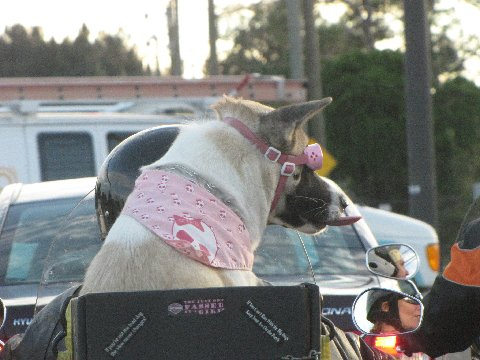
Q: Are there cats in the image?
A: No, there are no cats.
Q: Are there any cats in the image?
A: No, there are no cats.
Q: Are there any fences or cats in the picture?
A: No, there are no cats or fences.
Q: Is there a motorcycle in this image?
A: Yes, there is a motorcycle.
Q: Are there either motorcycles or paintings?
A: Yes, there is a motorcycle.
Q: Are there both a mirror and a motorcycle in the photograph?
A: Yes, there are both a motorcycle and a mirror.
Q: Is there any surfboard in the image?
A: No, there are no surfboards.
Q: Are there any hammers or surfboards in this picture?
A: No, there are no surfboards or hammers.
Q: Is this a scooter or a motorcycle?
A: This is a motorcycle.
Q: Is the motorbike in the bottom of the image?
A: Yes, the motorbike is in the bottom of the image.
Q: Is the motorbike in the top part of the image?
A: No, the motorbike is in the bottom of the image.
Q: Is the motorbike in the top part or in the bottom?
A: The motorbike is in the bottom of the image.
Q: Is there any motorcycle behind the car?
A: Yes, there is a motorcycle behind the car.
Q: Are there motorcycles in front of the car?
A: No, the motorcycle is behind the car.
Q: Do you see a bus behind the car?
A: No, there is a motorcycle behind the car.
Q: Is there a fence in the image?
A: No, there are no fences.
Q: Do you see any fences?
A: No, there are no fences.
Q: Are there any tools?
A: No, there are no tools.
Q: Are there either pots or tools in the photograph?
A: No, there are no tools or pots.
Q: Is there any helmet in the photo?
A: Yes, there is a helmet.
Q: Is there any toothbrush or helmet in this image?
A: Yes, there is a helmet.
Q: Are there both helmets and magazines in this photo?
A: No, there is a helmet but no magazines.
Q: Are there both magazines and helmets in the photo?
A: No, there is a helmet but no magazines.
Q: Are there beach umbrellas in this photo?
A: No, there are no beach umbrellas.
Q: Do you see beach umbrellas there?
A: No, there are no beach umbrellas.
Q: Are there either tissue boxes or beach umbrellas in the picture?
A: No, there are no beach umbrellas or tissue boxes.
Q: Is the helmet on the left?
A: Yes, the helmet is on the left of the image.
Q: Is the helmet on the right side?
A: No, the helmet is on the left of the image.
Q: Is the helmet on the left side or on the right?
A: The helmet is on the left of the image.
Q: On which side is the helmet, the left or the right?
A: The helmet is on the left of the image.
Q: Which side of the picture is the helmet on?
A: The helmet is on the left of the image.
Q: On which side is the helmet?
A: The helmet is on the left of the image.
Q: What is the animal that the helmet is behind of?
A: The animal is a dog.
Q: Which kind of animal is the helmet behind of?
A: The helmet is behind the dog.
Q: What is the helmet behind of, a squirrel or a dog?
A: The helmet is behind a dog.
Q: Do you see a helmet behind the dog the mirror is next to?
A: Yes, there is a helmet behind the dog.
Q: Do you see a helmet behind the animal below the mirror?
A: Yes, there is a helmet behind the dog.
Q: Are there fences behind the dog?
A: No, there is a helmet behind the dog.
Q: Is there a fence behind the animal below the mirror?
A: No, there is a helmet behind the dog.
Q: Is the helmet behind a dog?
A: Yes, the helmet is behind a dog.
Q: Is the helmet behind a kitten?
A: No, the helmet is behind a dog.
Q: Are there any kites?
A: No, there are no kites.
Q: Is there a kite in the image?
A: No, there are no kites.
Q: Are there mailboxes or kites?
A: No, there are no kites or mailboxes.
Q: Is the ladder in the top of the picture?
A: Yes, the ladder is in the top of the image.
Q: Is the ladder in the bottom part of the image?
A: No, the ladder is in the top of the image.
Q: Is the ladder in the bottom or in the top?
A: The ladder is in the top of the image.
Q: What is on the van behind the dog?
A: The ladder is on the van.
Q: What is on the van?
A: The ladder is on the van.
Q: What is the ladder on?
A: The ladder is on the van.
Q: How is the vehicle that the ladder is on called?
A: The vehicle is a van.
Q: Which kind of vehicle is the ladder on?
A: The ladder is on the van.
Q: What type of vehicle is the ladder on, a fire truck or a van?
A: The ladder is on a van.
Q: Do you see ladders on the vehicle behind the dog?
A: Yes, there is a ladder on the van.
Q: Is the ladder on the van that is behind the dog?
A: Yes, the ladder is on the van.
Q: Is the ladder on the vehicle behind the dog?
A: Yes, the ladder is on the van.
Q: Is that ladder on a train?
A: No, the ladder is on the van.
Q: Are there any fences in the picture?
A: No, there are no fences.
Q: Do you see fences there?
A: No, there are no fences.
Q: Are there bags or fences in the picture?
A: No, there are no fences or bags.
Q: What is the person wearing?
A: The person is wearing a helmet.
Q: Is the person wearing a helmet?
A: Yes, the person is wearing a helmet.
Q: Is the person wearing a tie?
A: No, the person is wearing a helmet.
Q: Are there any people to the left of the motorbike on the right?
A: Yes, there is a person to the left of the motorcycle.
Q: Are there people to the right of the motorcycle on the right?
A: No, the person is to the left of the motorbike.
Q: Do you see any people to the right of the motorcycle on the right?
A: No, the person is to the left of the motorbike.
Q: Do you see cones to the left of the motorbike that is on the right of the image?
A: No, there is a person to the left of the motorbike.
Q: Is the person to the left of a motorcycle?
A: Yes, the person is to the left of a motorcycle.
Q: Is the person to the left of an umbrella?
A: No, the person is to the left of a motorcycle.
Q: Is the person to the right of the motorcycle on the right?
A: No, the person is to the left of the motorbike.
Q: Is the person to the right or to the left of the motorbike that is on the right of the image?
A: The person is to the left of the motorbike.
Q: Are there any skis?
A: No, there are no skis.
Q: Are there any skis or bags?
A: No, there are no skis or bags.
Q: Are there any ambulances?
A: No, there are no ambulances.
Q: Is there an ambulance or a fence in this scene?
A: No, there are no ambulances or fences.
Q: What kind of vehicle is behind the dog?
A: The vehicle is a van.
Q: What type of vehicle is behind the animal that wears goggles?
A: The vehicle is a van.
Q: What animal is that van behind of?
A: The van is behind the dog.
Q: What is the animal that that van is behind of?
A: The animal is a dog.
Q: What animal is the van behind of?
A: The van is behind the dog.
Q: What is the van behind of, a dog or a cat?
A: The van is behind a dog.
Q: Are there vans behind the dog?
A: Yes, there is a van behind the dog.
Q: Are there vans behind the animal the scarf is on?
A: Yes, there is a van behind the dog.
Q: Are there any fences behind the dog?
A: No, there is a van behind the dog.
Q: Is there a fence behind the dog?
A: No, there is a van behind the dog.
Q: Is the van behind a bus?
A: No, the van is behind the dog.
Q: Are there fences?
A: No, there are no fences.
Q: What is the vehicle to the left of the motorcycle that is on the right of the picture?
A: The vehicle is a car.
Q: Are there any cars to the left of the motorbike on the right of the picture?
A: Yes, there is a car to the left of the motorbike.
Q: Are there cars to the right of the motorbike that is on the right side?
A: No, the car is to the left of the motorbike.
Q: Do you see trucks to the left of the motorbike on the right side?
A: No, there is a car to the left of the motorbike.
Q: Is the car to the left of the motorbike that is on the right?
A: Yes, the car is to the left of the motorcycle.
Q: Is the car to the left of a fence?
A: No, the car is to the left of the motorcycle.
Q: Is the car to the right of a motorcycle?
A: No, the car is to the left of a motorcycle.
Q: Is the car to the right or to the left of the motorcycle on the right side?
A: The car is to the left of the motorcycle.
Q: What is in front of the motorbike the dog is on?
A: The car is in front of the motorcycle.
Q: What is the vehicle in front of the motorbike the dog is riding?
A: The vehicle is a car.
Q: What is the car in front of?
A: The car is in front of the motorcycle.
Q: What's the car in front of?
A: The car is in front of the motorcycle.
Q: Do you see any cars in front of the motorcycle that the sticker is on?
A: Yes, there is a car in front of the motorbike.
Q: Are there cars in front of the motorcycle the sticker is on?
A: Yes, there is a car in front of the motorbike.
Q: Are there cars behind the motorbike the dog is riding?
A: No, the car is in front of the motorbike.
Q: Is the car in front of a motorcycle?
A: Yes, the car is in front of a motorcycle.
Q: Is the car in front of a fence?
A: No, the car is in front of a motorcycle.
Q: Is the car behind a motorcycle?
A: No, the car is in front of a motorcycle.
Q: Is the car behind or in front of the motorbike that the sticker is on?
A: The car is in front of the motorbike.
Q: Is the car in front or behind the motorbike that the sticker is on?
A: The car is in front of the motorbike.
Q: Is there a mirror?
A: Yes, there is a mirror.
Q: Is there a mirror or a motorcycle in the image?
A: Yes, there is a mirror.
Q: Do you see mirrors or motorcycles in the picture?
A: Yes, there is a mirror.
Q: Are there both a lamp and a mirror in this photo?
A: No, there is a mirror but no lamps.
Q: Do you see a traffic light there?
A: No, there are no traffic lights.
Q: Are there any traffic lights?
A: No, there are no traffic lights.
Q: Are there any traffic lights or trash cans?
A: No, there are no traffic lights or trash cans.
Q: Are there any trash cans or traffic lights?
A: No, there are no traffic lights or trash cans.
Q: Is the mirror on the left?
A: No, the mirror is on the right of the image.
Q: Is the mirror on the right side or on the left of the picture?
A: The mirror is on the right of the image.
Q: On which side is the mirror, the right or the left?
A: The mirror is on the right of the image.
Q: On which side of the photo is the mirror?
A: The mirror is on the right of the image.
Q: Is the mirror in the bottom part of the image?
A: Yes, the mirror is in the bottom of the image.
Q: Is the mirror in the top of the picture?
A: No, the mirror is in the bottom of the image.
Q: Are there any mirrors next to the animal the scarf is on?
A: Yes, there is a mirror next to the dog.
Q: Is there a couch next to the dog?
A: No, there is a mirror next to the dog.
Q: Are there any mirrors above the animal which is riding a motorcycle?
A: Yes, there is a mirror above the dog.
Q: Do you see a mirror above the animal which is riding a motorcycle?
A: Yes, there is a mirror above the dog.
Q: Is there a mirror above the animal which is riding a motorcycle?
A: Yes, there is a mirror above the dog.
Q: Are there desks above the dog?
A: No, there is a mirror above the dog.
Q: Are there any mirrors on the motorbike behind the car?
A: Yes, there is a mirror on the motorcycle.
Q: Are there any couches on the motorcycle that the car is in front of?
A: No, there is a mirror on the motorcycle.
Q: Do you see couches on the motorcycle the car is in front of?
A: No, there is a mirror on the motorcycle.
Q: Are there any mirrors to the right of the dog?
A: Yes, there is a mirror to the right of the dog.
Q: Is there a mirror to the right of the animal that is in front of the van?
A: Yes, there is a mirror to the right of the dog.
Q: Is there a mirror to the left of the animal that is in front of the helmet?
A: No, the mirror is to the right of the dog.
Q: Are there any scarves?
A: Yes, there is a scarf.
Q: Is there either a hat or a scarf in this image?
A: Yes, there is a scarf.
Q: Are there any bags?
A: No, there are no bags.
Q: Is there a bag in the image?
A: No, there are no bags.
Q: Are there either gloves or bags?
A: No, there are no bags or gloves.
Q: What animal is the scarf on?
A: The scarf is on the dog.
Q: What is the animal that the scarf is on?
A: The animal is a dog.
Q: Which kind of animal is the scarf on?
A: The scarf is on the dog.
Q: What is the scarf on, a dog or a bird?
A: The scarf is on a dog.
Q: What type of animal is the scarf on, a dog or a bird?
A: The scarf is on a dog.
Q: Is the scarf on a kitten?
A: No, the scarf is on a dog.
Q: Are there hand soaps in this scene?
A: No, there are no hand soaps.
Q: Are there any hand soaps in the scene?
A: No, there are no hand soaps.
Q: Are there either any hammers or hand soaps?
A: No, there are no hand soaps or hammers.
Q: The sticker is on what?
A: The sticker is on the motorcycle.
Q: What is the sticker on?
A: The sticker is on the motorcycle.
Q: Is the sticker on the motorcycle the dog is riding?
A: Yes, the sticker is on the motorcycle.